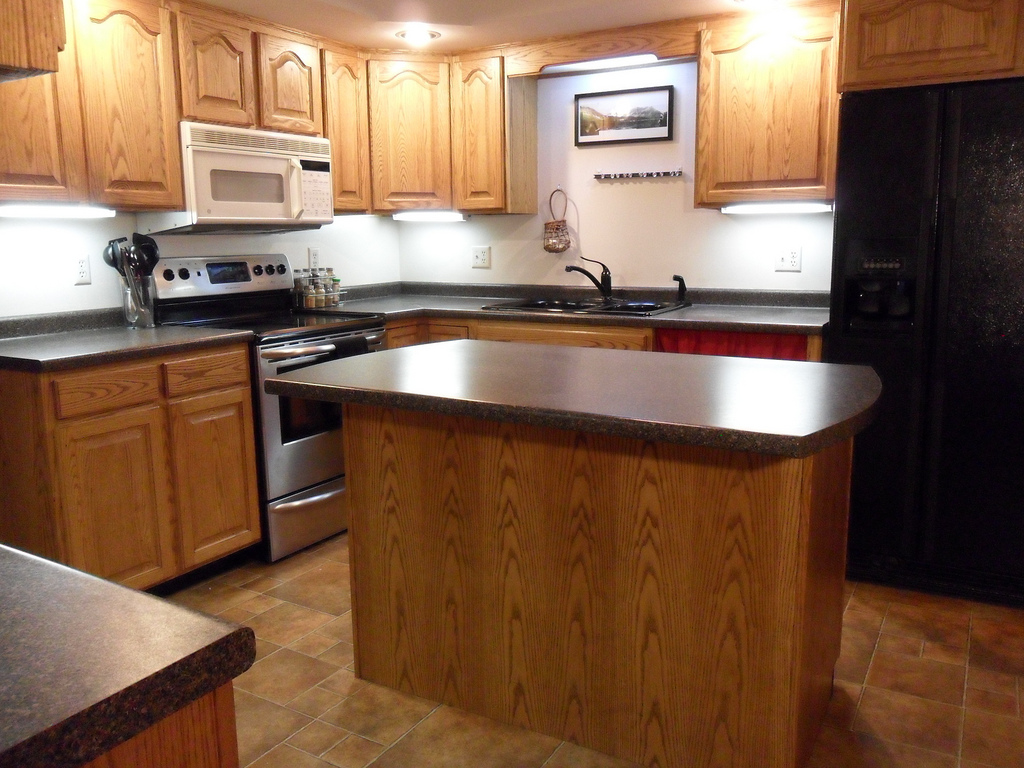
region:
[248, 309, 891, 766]
island counter in kitchen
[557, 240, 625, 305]
faucet above kitchen sink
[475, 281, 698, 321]
sink set in counter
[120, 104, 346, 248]
microwave above oven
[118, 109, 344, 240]
microwave in kitchen is white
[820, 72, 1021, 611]
refrigerator next to counter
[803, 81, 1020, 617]
refrigerator in kitchen is black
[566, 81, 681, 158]
picture on wall above sink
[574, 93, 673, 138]
a picture on the wall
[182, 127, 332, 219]
a white microwave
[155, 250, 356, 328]
the range on the oven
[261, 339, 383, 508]
the oven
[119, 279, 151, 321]
a glass bowl on the counter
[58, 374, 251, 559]
wooden cabinets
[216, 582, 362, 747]
brown tile on the floor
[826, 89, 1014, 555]
a black refrigerator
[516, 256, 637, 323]
a sink in the kitchen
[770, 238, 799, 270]
an electrical outlet on the wall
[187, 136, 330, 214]
a white microwave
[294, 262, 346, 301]
bottles on the counter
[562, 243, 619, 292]
the faucet on the sink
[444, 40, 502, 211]
wooden cabinet door in kitchen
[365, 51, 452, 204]
wooden cabinet door in kitchen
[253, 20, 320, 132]
wooden cabinet door in kitchen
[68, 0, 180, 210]
wooden cabinet door in kitchen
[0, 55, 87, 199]
wooden cabinet door in kitchen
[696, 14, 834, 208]
wooden cabinet door in kitchen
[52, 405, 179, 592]
wooden cabinet door in kitchen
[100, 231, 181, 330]
Utensils on the counter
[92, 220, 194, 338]
Utensils are on the counter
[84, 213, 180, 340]
Kitchen utensils on the counter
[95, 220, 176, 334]
Kitchen utensils are on the counter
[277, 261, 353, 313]
Spices are in a rack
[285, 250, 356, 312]
Spices are in a spice rack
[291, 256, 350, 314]
Spice rack on the counter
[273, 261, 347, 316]
Spice rack is on the counter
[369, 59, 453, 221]
cabinet is light brown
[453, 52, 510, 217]
cabinet is light brown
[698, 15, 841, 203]
cabinet is light brown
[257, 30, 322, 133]
cabinet is light brown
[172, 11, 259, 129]
cabinet is light brown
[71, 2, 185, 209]
cabinet is light brown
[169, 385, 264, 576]
cabinet is light brown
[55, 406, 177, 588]
cabinet is light brown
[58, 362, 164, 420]
cabinet is light brown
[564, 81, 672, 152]
picture hanging above sink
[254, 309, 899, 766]
island in middle of kitchen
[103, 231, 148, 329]
glass of cooking utensils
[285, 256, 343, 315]
rack of spices by stove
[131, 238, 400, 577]
stove and oven under microwave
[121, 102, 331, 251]
microwave above stove top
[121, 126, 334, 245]
microwave above stove is white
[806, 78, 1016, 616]
refrigerator by counter is black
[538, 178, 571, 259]
decor hanging above sink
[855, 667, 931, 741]
brown tile on the ground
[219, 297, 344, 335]
stove in between the counters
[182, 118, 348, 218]
microwave above the stove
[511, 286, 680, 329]
kitchen sink in the counter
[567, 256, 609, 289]
black metal faucet on the sink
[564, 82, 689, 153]
picture hanging on the wall